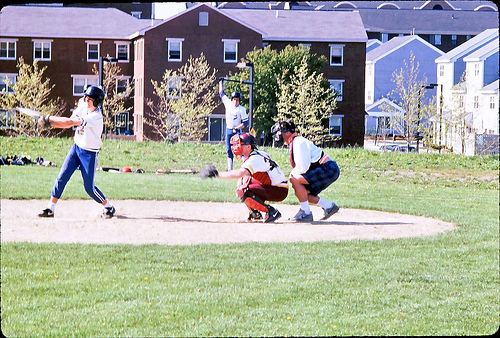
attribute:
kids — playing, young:
[39, 77, 339, 222]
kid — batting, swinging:
[39, 86, 115, 218]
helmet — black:
[84, 85, 105, 105]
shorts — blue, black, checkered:
[301, 160, 339, 196]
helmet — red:
[239, 132, 257, 147]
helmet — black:
[278, 121, 297, 133]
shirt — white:
[73, 97, 103, 150]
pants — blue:
[48, 145, 107, 203]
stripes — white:
[93, 188, 107, 203]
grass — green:
[0, 165, 498, 335]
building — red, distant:
[133, 2, 365, 148]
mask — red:
[230, 134, 243, 159]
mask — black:
[271, 121, 284, 148]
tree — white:
[390, 50, 425, 152]